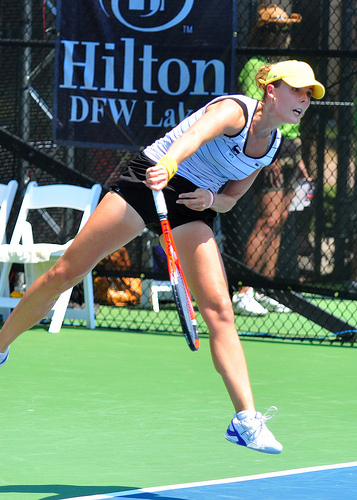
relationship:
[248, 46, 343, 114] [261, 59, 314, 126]
yellow cap covering head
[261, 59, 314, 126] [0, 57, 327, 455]
head belonging to tennis player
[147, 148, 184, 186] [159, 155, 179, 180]
yellow band worn around wrist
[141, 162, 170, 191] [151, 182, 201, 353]
hand holding hockey stick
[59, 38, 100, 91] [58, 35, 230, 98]
letter forming hilton sign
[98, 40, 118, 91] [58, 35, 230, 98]
letter forming hilton sign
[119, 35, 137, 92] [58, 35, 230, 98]
letter forming hilton sign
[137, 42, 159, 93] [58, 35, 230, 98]
letter forming hilton sign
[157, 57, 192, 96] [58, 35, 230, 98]
letter forming hilton sign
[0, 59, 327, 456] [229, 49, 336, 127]
tennis player wearing yellow cap